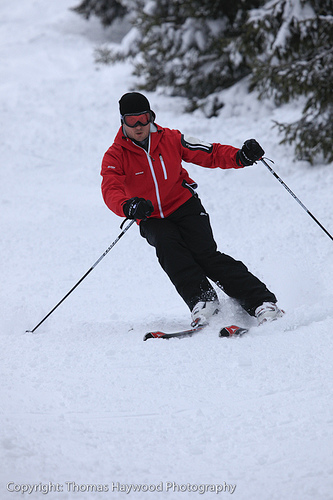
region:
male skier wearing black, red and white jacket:
[103, 137, 230, 197]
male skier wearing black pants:
[137, 223, 255, 297]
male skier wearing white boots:
[187, 294, 216, 324]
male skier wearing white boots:
[249, 302, 278, 318]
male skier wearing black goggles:
[117, 110, 161, 122]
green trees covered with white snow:
[131, 3, 311, 89]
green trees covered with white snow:
[271, 8, 324, 140]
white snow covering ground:
[12, 343, 308, 463]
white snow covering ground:
[4, 7, 70, 256]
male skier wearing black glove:
[123, 199, 146, 215]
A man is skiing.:
[71, 87, 289, 358]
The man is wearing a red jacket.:
[69, 126, 266, 215]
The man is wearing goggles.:
[111, 109, 157, 126]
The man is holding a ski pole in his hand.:
[21, 187, 150, 348]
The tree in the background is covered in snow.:
[97, 4, 326, 77]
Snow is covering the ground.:
[34, 378, 317, 457]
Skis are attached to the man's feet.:
[122, 276, 298, 363]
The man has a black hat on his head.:
[110, 81, 157, 115]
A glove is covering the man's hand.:
[107, 191, 161, 223]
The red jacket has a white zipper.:
[137, 143, 170, 219]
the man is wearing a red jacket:
[97, 126, 252, 228]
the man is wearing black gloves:
[222, 130, 263, 174]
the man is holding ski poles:
[54, 144, 321, 321]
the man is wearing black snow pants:
[128, 205, 282, 320]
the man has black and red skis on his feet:
[125, 291, 285, 354]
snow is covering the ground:
[31, 292, 308, 425]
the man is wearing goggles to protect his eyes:
[118, 108, 156, 133]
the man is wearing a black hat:
[108, 96, 157, 116]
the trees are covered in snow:
[75, 1, 323, 134]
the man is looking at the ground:
[89, 101, 196, 152]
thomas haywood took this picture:
[4, 468, 242, 494]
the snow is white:
[1, 0, 330, 497]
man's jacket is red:
[85, 130, 239, 221]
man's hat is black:
[105, 90, 152, 110]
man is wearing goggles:
[107, 108, 168, 139]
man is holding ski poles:
[0, 150, 329, 354]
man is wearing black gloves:
[96, 141, 308, 233]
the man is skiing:
[66, 81, 329, 362]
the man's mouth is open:
[124, 123, 154, 141]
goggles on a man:
[111, 110, 167, 132]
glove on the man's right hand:
[116, 188, 158, 227]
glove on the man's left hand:
[227, 133, 272, 169]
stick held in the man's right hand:
[12, 196, 152, 352]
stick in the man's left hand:
[240, 135, 332, 250]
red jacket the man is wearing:
[83, 126, 253, 222]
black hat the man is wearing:
[104, 87, 162, 118]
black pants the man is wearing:
[129, 190, 288, 323]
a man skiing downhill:
[88, 84, 298, 368]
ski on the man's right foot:
[127, 282, 222, 348]